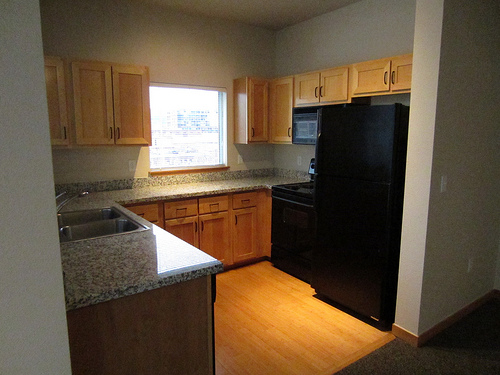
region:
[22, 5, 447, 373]
Kitchen in a house.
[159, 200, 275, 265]
Cabinets under the counter.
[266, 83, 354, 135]
Microwave above the stove.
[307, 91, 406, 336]
Black refrigerator in the kitchen.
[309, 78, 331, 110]
Handles on the cabinet.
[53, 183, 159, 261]
Sink in the counter.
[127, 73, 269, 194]
Window over the counter.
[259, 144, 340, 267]
stove in the kitchen.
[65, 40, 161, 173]
Cabinet on the wall.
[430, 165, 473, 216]
Light switch on the wall.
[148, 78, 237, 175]
window in kitchen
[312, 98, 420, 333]
new black refrigerator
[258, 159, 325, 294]
new black stove with oven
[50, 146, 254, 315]
brown speckled granite counter tops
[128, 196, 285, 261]
new woden cabinets with metal knobs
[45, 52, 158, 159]
new woden cabinets with metal knobs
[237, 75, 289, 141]
new woden cabinets with metal knobs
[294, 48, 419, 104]
new woden cabinets with metal knobs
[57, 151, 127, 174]
beige tile backsplash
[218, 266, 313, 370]
medium brown hardwood floor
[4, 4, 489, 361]
A kitchen scene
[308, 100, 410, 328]
A black refrigerator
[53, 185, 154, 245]
A kitchen sink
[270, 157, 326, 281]
A stove is beside the refrigerator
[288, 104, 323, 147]
A microwave oven is above the stove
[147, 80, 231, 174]
The kitchen window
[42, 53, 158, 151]
Wooden kitchen cabinets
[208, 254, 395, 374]
The floor is wood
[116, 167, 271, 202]
The kitchen counter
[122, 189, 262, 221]
Drawers are under the counter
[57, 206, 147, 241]
double stainless steel sink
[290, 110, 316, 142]
black microwave oven in kitchen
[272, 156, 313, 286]
black stove and oven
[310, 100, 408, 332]
black refrigerator in kitcehn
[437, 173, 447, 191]
white lightswitch in hallway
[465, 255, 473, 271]
white electrical plug in hallway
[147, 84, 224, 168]
window covered with miniblinds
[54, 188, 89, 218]
stainless steel faucet and handle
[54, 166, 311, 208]
granite countertop under window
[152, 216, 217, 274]
sunlight on granite countertop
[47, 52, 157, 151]
pale wood kitchen cabinets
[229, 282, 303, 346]
pale wood plank kitchen floor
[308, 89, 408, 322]
black refrigerator in the kitchen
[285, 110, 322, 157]
microwave above the black stove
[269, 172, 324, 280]
black stove next to the refrigerator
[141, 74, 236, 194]
window over the kitchen counter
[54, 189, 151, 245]
double sink in the kitchen counter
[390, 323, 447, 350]
pale wood base boards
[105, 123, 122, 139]
black handles on the cabinets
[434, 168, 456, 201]
light switch on wall outside of kitchen